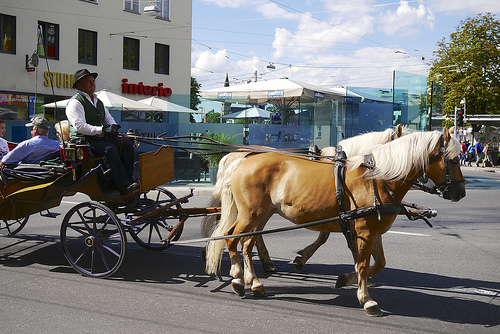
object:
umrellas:
[198, 77, 361, 101]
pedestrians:
[418, 95, 495, 190]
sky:
[190, 0, 499, 91]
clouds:
[191, 1, 498, 103]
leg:
[239, 237, 255, 276]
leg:
[224, 215, 252, 276]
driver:
[65, 68, 139, 193]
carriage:
[2, 142, 440, 279]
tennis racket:
[196, 122, 468, 319]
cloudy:
[274, 6, 439, 61]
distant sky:
[200, 7, 429, 82]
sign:
[42, 70, 78, 88]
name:
[43, 67, 76, 89]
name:
[121, 78, 174, 96]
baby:
[120, 32, 146, 74]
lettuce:
[150, 37, 175, 81]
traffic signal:
[456, 110, 463, 126]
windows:
[122, 1, 172, 21]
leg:
[353, 221, 376, 297]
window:
[2, 13, 20, 53]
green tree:
[422, 9, 497, 116]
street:
[12, 225, 495, 334]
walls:
[0, 69, 182, 147]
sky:
[194, 5, 496, 109]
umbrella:
[42, 89, 162, 112]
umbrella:
[137, 94, 199, 114]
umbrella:
[214, 105, 276, 120]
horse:
[200, 123, 412, 273]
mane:
[332, 121, 413, 156]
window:
[122, 35, 141, 75]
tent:
[206, 75, 369, 128]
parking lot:
[0, 95, 498, 333]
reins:
[117, 129, 339, 162]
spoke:
[58, 200, 128, 278]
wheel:
[120, 184, 186, 252]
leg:
[306, 231, 332, 253]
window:
[37, 18, 61, 60]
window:
[77, 27, 99, 66]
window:
[154, 41, 171, 76]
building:
[2, 1, 243, 182]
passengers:
[0, 118, 14, 154]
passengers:
[0, 117, 61, 165]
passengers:
[54, 120, 70, 141]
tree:
[427, 7, 497, 142]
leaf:
[484, 46, 497, 58]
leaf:
[490, 23, 493, 28]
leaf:
[452, 87, 457, 90]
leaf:
[451, 57, 455, 64]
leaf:
[462, 51, 469, 56]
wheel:
[60, 194, 133, 279]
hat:
[71, 68, 98, 88]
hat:
[23, 115, 54, 132]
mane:
[329, 119, 440, 186]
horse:
[205, 124, 467, 283]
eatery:
[9, 70, 190, 183]